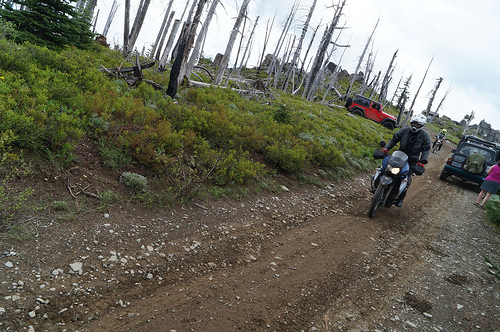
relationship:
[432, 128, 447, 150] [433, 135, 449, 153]
man on top of motorcycle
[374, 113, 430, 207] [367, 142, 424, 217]
person on top of motorcycle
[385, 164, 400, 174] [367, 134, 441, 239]
headlight on motorcycle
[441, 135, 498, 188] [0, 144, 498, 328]
car on road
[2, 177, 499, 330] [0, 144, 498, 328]
rocks in road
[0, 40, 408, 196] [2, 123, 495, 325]
shrubs off side of road